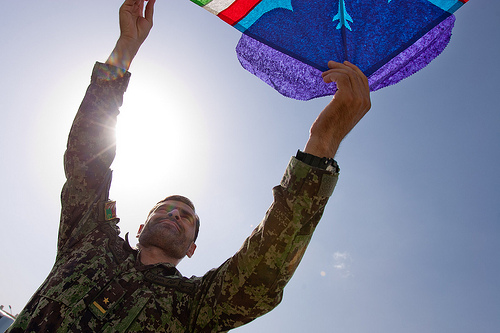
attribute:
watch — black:
[297, 147, 341, 177]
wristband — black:
[295, 147, 340, 176]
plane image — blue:
[332, 1, 354, 31]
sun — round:
[44, 74, 189, 194]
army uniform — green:
[4, 60, 340, 330]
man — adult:
[13, 0, 375, 330]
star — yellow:
[102, 297, 108, 304]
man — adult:
[41, 48, 345, 330]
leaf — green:
[243, 277, 270, 307]